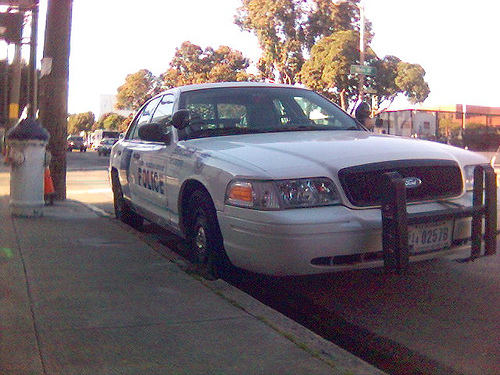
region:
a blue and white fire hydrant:
[10, 109, 56, 219]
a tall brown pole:
[35, 0, 73, 199]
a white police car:
[108, 80, 498, 284]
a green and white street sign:
[347, 60, 379, 76]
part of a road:
[66, 140, 120, 210]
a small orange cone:
[41, 162, 56, 192]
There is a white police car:
[106, 80, 499, 284]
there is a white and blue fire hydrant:
[3, 116, 55, 215]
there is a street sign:
[350, 49, 380, 98]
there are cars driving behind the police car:
[68, 125, 114, 152]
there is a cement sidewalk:
[3, 218, 388, 373]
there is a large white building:
[375, 100, 496, 154]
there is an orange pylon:
[41, 158, 57, 203]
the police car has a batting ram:
[376, 165, 498, 260]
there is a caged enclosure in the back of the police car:
[145, 87, 295, 129]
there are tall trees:
[71, 0, 431, 151]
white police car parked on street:
[107, 72, 494, 279]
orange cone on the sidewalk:
[45, 161, 58, 206]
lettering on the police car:
[137, 151, 167, 196]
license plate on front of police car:
[415, 220, 450, 248]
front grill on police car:
[350, 152, 457, 202]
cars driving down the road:
[69, 129, 114, 154]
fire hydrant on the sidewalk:
[2, 119, 62, 221]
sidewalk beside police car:
[5, 160, 367, 370]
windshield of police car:
[180, 94, 343, 135]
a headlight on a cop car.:
[222, 171, 345, 217]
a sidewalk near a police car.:
[0, 182, 386, 372]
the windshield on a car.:
[180, 83, 364, 133]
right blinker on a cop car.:
[225, 171, 259, 209]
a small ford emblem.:
[396, 173, 430, 192]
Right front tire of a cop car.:
[167, 184, 227, 278]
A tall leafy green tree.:
[233, 0, 438, 120]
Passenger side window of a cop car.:
[145, 90, 183, 149]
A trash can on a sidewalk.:
[5, 114, 58, 213]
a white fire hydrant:
[3, 100, 57, 225]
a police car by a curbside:
[112, 84, 497, 296]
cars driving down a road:
[66, 120, 127, 174]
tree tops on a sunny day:
[110, 3, 428, 93]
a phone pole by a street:
[26, 1, 77, 219]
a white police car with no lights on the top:
[100, 80, 498, 284]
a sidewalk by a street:
[0, 195, 388, 372]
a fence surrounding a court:
[372, 98, 499, 160]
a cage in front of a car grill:
[376, 161, 498, 275]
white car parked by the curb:
[108, 80, 498, 288]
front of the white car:
[246, 150, 482, 263]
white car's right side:
[108, 88, 239, 265]